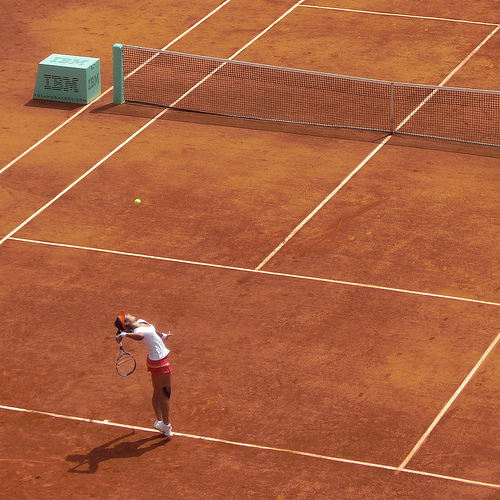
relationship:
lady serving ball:
[113, 309, 175, 438] [126, 188, 152, 212]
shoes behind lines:
[152, 417, 177, 439] [0, 397, 480, 481]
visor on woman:
[117, 308, 128, 328] [110, 300, 202, 470]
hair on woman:
[116, 310, 145, 325] [93, 304, 202, 456]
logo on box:
[42, 76, 82, 93] [35, 51, 109, 109]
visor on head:
[110, 311, 128, 329] [106, 287, 138, 343]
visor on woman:
[110, 311, 128, 329] [102, 297, 192, 462]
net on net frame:
[119, 37, 499, 177] [112, 45, 129, 107]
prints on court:
[326, 310, 452, 391] [26, 16, 420, 366]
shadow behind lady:
[70, 423, 156, 467] [113, 309, 175, 438]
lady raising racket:
[113, 309, 175, 438] [105, 348, 147, 372]